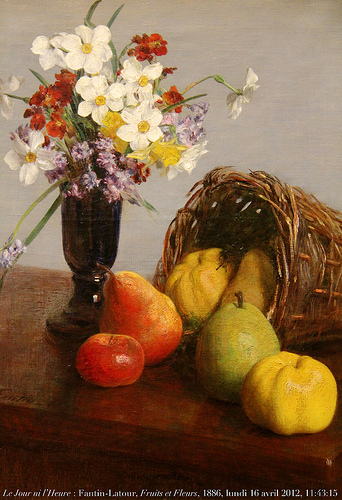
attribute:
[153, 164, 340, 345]
basket — straw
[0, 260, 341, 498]
table — wooden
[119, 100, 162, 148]
daisy — white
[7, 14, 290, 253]
picture — realistic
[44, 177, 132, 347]
vase — brown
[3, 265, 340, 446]
table — wooden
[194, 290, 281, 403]
pear — green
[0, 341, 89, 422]
table — brown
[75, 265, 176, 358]
pear — red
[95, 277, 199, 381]
pear — painted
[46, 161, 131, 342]
vase — painted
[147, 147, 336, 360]
basket — painted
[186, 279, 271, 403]
pear — green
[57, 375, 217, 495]
table — wooden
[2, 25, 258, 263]
flowers — many colors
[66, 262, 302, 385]
apples — red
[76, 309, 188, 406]
apple — painted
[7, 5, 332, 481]
painting — still life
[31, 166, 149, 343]
vase — brown